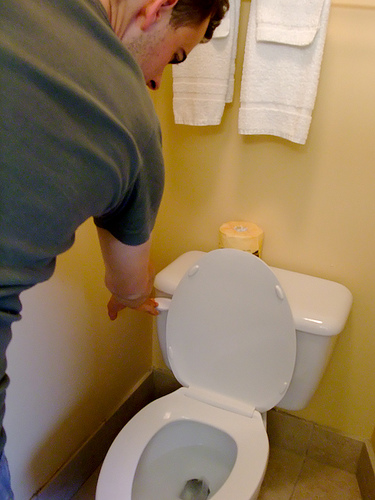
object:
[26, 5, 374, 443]
wall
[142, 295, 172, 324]
handle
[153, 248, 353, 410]
water tank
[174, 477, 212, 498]
hole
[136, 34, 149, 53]
facial hair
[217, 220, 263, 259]
wrapper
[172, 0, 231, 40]
hair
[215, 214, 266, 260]
roll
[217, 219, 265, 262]
toilet paper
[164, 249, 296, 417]
lid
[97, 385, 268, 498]
toilet seat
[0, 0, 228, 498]
man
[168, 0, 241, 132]
towels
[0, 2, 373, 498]
bathroom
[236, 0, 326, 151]
cloth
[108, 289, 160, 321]
hand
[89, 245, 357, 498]
toilet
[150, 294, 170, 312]
hand flushing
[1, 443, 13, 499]
blue jeans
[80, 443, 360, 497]
tiled flooring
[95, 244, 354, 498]
toilet bowl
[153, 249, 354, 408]
commode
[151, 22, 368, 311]
rack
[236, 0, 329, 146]
towels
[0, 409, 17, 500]
jeans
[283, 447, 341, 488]
tile floor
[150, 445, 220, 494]
water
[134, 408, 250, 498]
bowl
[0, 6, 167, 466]
shirt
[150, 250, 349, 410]
tank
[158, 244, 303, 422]
top